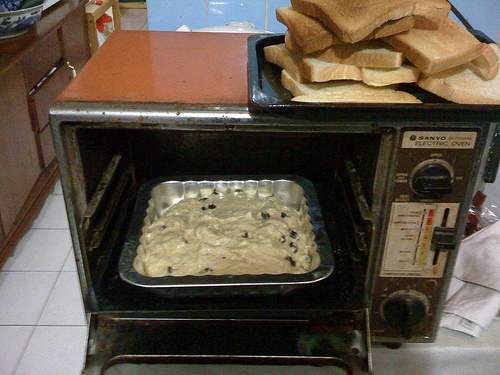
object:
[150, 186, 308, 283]
potatoes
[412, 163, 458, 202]
knob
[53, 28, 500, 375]
microwave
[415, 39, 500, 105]
bread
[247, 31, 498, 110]
pan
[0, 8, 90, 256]
drawers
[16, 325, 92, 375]
tile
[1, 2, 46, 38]
bowl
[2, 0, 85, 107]
counter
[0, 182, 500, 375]
floor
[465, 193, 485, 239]
utensil